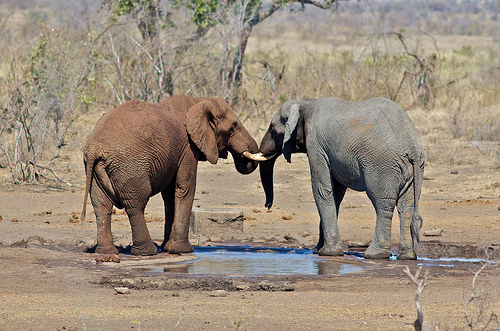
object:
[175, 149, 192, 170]
lines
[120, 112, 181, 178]
skin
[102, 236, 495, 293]
puddle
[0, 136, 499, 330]
ground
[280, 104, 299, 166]
ear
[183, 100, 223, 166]
ear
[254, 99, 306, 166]
head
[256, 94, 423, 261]
elephant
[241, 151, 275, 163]
tusk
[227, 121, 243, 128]
eye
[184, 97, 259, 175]
head